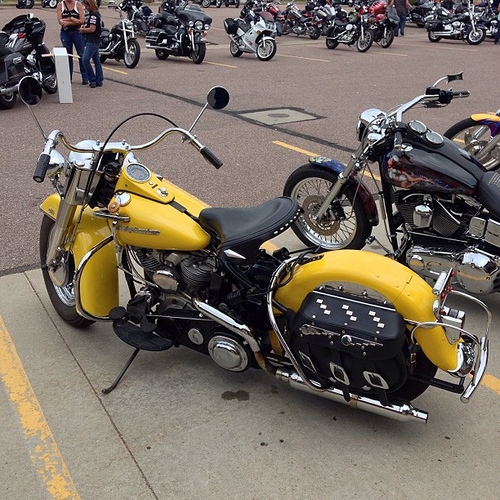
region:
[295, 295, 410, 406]
leather saddle bag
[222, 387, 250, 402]
oil spot on the ground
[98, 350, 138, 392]
black kick stand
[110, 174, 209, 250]
yellow gas tank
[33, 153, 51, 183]
black handle grip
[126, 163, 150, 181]
speed gauge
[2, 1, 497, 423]
parking lot full of motorcycles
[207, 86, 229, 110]
round side mirror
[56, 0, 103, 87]
two women standing near each other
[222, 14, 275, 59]
a white street bike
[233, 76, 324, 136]
square of cement with grate in parking lot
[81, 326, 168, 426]
black metal kick stand on bike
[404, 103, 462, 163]
gas and speed gauges on black motorcycle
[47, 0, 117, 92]
twp women observing displayed motorcycles in lot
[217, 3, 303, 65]
white motorcycle with black rubber tires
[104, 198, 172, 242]
chrome logo on yellow painted bike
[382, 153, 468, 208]
airbrushed design on black painted motorcycle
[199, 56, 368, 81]
yellow lines painted on ground for parking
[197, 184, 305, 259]
black leather seat with silver studs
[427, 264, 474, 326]
red lights on back of chrome piece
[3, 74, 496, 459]
yellow motorcycle in parking space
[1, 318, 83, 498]
yellow line on parking space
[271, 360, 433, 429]
metal tailpipe on motorcycle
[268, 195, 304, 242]
studs on back of leather black motorcycle seat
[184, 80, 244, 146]
rear view mirror on motorcyle handlebar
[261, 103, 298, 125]
metal top on parking lot surface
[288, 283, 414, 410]
black case on side of motorcycle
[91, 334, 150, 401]
kick stand on side of motorcycle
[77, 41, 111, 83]
pair of blue jeans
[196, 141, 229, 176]
black tip of handlebars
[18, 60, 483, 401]
lot with motorized bikes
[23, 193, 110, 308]
front tire on motorized bike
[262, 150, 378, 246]
front tire on motorized bike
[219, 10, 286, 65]
motorized bike on lot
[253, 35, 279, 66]
front tire on motorized bike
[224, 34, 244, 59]
rear tire on motorized bike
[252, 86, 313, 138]
covering on the lot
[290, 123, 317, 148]
tar in the lot crevice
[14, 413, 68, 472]
yellow strip separating lanes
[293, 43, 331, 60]
empty spot with no bike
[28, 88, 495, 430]
Yellow and black motorbike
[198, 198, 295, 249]
Black seat of motorbike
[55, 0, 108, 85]
Two women standing beside bikes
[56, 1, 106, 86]
Women dressed in jeans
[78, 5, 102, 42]
Woman in a black t-shirt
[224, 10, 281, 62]
White and black motorbike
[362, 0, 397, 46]
Red and black motorbike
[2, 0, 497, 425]
Motorbikes put on display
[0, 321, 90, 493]
Yellow mark on parking lot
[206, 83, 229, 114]
Round side mirror of bike